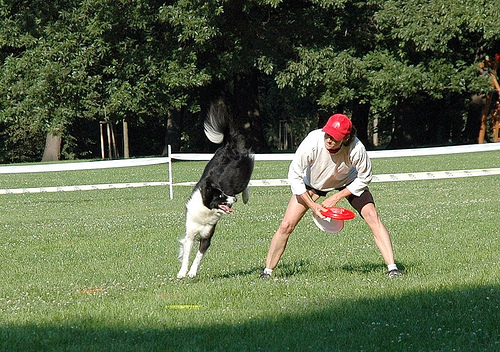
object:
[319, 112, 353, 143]
cap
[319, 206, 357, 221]
frisbee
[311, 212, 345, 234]
frisbee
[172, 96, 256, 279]
dog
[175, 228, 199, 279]
leg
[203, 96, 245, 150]
tail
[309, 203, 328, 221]
hand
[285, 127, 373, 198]
shirt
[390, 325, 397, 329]
flower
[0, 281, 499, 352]
shade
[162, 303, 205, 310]
patch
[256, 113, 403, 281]
person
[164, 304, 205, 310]
frisbee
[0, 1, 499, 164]
tree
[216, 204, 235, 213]
tongue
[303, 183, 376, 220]
shorts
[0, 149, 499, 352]
grass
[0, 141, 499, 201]
fence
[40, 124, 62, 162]
trunk